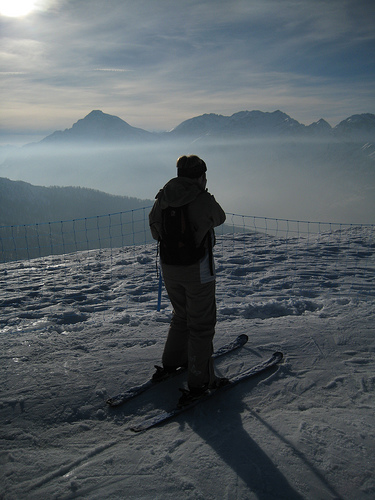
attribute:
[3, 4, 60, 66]
sun — shining, bright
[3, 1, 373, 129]
sky — cloudy, blue, sunny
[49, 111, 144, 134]
mountain — hazy, dark, view, distant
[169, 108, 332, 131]
mountain — tree lined, dark, distant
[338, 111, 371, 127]
mountain — hazy, distant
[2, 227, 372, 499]
snow — white, covering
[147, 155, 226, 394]
person — observing, standing, skiing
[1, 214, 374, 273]
fence — net, plastic, blue, safety net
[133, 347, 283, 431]
ski — snow covered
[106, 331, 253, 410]
ski — snow covered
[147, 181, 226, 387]
snow suit — tan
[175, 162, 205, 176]
head band — warm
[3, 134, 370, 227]
mist — white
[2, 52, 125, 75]
cloud — white, thin